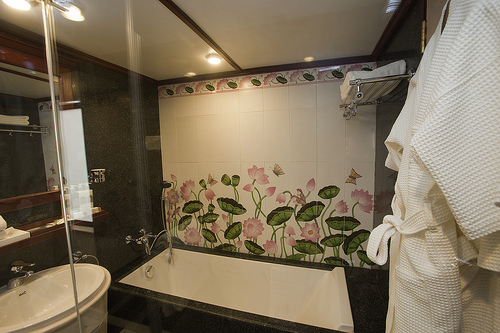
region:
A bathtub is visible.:
[130, 214, 234, 308]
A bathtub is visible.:
[181, 242, 232, 310]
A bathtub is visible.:
[158, 245, 250, 330]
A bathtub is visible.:
[227, 272, 299, 330]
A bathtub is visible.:
[160, 237, 197, 288]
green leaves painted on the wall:
[215, 190, 247, 222]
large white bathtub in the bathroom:
[116, 217, 368, 331]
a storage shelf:
[332, 43, 413, 134]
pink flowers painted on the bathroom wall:
[239, 157, 275, 198]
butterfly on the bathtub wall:
[267, 160, 289, 178]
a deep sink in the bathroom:
[0, 244, 115, 331]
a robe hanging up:
[370, 30, 497, 332]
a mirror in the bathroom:
[2, 59, 77, 237]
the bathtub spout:
[125, 216, 190, 258]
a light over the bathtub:
[196, 47, 232, 75]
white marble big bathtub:
[122, 220, 424, 330]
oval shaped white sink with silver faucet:
[0, 211, 117, 331]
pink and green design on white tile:
[151, 134, 389, 281]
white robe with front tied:
[371, 11, 475, 327]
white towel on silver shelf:
[330, 43, 414, 138]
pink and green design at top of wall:
[154, 66, 421, 102]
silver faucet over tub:
[114, 216, 191, 272]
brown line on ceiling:
[144, 0, 266, 81]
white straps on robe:
[360, 199, 456, 273]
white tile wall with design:
[150, 81, 392, 278]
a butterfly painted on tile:
[337, 166, 362, 187]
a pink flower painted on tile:
[246, 162, 267, 179]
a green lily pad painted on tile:
[322, 214, 362, 232]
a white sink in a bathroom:
[2, 252, 97, 328]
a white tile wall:
[180, 102, 322, 137]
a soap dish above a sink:
[0, 216, 31, 251]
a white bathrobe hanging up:
[362, 0, 494, 325]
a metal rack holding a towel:
[330, 50, 416, 126]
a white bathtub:
[122, 231, 348, 329]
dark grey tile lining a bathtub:
[118, 287, 218, 329]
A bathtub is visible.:
[135, 228, 317, 318]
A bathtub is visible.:
[211, 251, 281, 312]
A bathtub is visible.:
[165, 200, 266, 318]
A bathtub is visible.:
[227, 204, 289, 314]